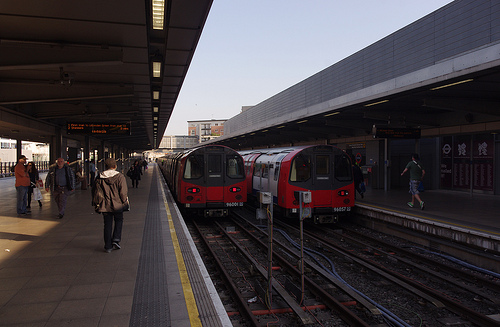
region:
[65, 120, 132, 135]
a sign on the train platform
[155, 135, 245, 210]
a red train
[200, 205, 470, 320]
the train tracks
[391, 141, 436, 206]
a person walking next to the train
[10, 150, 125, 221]
people standing on the train platform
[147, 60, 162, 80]
a light in the ceiling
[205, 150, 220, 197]
a door on the train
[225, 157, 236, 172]
a window on the train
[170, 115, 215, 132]
a building behind the trains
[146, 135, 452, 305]
two trains on the tracks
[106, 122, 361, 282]
view is at a train station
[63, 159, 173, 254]
man walking towards the train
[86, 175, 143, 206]
the jacket is grey in color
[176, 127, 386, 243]
two trains are in motion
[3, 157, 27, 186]
the jacket is red in color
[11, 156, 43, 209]
man and a woman standing at the train station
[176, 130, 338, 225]
the train are same in color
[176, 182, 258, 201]
the train lights are on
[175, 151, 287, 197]
the train head is rd in color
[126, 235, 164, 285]
part of a floor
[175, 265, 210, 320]
pasrt of a line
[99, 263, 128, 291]
part of a floor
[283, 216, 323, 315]
part of a stand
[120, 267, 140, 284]
part of a floor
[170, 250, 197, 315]
part of a oin e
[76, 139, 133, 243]
the body of a man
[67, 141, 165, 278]
the body of a man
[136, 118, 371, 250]
two passenger trains stopped at a station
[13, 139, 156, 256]
people at a train station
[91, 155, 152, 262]
a man walking down a sidewalk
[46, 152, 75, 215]
a man walking down a sidewalk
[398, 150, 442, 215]
a man walking quickly down a sidewalk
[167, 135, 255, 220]
the back of a passenger train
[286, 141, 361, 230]
the back of a passenger train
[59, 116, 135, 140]
a sign at a railway station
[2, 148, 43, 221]
a man and woman standing next to one another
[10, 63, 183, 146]
the awning at a train station